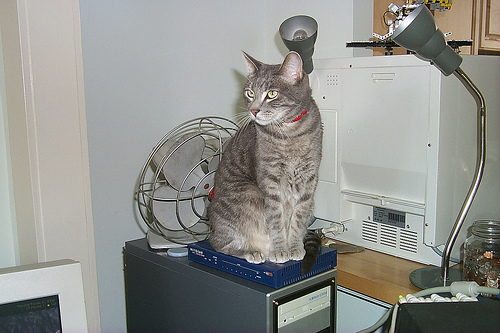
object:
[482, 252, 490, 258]
coins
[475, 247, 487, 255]
coins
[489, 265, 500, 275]
coins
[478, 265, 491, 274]
coins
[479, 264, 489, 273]
coins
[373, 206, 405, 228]
plate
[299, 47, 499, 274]
fridge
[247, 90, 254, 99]
eye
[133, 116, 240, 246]
fan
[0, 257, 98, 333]
frame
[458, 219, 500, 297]
jar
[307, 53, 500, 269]
machine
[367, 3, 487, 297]
lamp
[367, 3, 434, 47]
figure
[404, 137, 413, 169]
ground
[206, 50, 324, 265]
cat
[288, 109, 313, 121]
collar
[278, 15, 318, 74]
lamp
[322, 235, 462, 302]
desk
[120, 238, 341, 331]
computer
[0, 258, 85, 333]
monitor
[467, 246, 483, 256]
coins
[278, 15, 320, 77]
desk lamp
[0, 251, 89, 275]
edge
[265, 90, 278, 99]
eye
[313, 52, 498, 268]
fridge